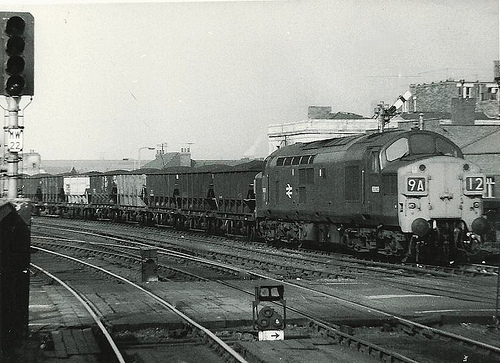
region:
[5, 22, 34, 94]
stoplight near the tracks.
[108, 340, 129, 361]
track made of steel.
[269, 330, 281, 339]
arrow on the sign.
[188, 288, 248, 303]
walkway across the tracks.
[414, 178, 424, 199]
letter on the train.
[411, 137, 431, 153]
windshield on the train.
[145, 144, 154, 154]
light on the pole.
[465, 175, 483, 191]
number on the train.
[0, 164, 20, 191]
pole supporting the light.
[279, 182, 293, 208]
white paint on the train.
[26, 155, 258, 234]
Coal in train cars on the tracks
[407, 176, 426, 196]
Numbers on the front of a train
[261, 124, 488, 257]
The front car of the train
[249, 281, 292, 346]
A train signal on the tracks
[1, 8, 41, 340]
A stoplight near the tracks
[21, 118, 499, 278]
A train on the tracks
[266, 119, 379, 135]
The top of a white building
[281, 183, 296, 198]
A white train logo on the side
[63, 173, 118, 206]
A white train car next to a darker one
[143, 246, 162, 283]
A black box on the tracks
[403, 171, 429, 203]
number 9A on front of train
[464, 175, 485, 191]
number 12 on front of train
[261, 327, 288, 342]
right direction arrow for train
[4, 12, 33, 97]
stop and go lights for train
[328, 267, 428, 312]
railway crossing trough the tracks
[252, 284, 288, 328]
equipment to change track direction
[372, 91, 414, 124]
shoot for loading coal in train cars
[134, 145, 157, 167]
street light for train tracks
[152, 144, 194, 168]
black roof of building in distance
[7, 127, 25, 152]
mw 22 sign under train lights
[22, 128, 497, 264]
Train on the tracks.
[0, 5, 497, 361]
A black and white photograph.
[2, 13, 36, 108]
Signal lights on the side of the tracks.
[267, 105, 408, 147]
Building behind the train.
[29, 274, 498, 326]
Road crossing the tracks.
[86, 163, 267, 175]
Black coal in the freight cars.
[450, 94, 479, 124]
Brick chimney on the roof.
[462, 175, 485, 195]
White number on the train.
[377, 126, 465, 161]
Front windows on the train.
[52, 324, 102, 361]
Wood planks beside tracks.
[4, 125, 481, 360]
the picture is black and white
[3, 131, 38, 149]
the numbers are 22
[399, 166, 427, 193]
9a is in white color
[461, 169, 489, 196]
the number is 12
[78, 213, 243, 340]
the railtracks are mettalic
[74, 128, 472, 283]
the train is old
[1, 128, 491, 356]
the scene is outdoors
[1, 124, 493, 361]
picture was taken during the day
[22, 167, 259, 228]
carts are behind the train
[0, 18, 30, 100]
the traffic light is off